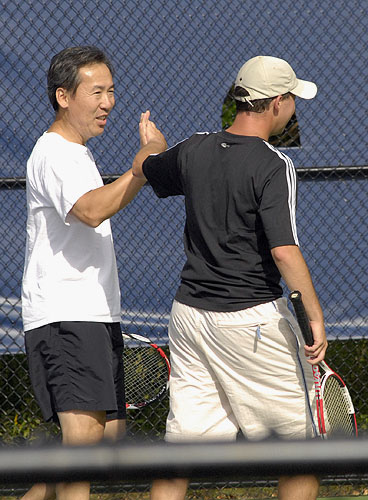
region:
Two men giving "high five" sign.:
[22, 25, 349, 498]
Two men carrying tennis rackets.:
[25, 46, 361, 498]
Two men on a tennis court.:
[23, 27, 365, 498]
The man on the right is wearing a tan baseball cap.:
[135, 47, 366, 498]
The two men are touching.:
[11, 38, 365, 499]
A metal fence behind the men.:
[2, 2, 365, 495]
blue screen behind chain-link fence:
[4, 7, 361, 476]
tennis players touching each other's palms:
[24, 43, 316, 232]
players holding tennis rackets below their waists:
[19, 48, 359, 435]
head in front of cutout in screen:
[215, 53, 317, 152]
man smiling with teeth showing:
[43, 43, 117, 140]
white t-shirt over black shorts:
[19, 132, 134, 423]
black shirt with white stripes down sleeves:
[142, 130, 302, 312]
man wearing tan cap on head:
[230, 53, 318, 132]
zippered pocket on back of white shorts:
[164, 296, 330, 443]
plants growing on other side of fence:
[2, 341, 363, 496]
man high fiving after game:
[142, 53, 363, 498]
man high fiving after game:
[18, 46, 146, 499]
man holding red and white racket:
[287, 285, 362, 442]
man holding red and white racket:
[118, 331, 173, 411]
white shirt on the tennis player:
[15, 129, 130, 326]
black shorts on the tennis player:
[16, 319, 130, 418]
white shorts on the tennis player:
[161, 297, 323, 438]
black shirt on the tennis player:
[139, 126, 302, 313]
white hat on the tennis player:
[227, 53, 319, 107]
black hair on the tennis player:
[46, 44, 115, 109]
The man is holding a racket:
[253, 298, 362, 438]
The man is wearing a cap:
[232, 51, 325, 107]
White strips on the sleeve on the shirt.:
[274, 149, 304, 236]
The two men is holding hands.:
[120, 101, 159, 174]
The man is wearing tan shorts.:
[168, 325, 286, 427]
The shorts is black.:
[11, 327, 136, 404]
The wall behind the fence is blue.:
[121, 31, 350, 266]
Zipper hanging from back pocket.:
[247, 321, 282, 358]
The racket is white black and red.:
[308, 360, 354, 439]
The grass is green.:
[0, 362, 58, 434]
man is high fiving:
[16, 46, 158, 498]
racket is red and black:
[121, 327, 169, 411]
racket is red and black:
[290, 290, 359, 438]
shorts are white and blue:
[164, 297, 323, 439]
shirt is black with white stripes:
[143, 131, 302, 311]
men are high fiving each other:
[22, 44, 359, 498]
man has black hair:
[46, 47, 113, 112]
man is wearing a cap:
[231, 55, 318, 107]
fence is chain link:
[0, 34, 365, 498]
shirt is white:
[21, 131, 122, 330]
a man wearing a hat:
[228, 50, 318, 105]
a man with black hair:
[45, 46, 120, 98]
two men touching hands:
[138, 103, 167, 160]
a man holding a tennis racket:
[288, 267, 358, 444]